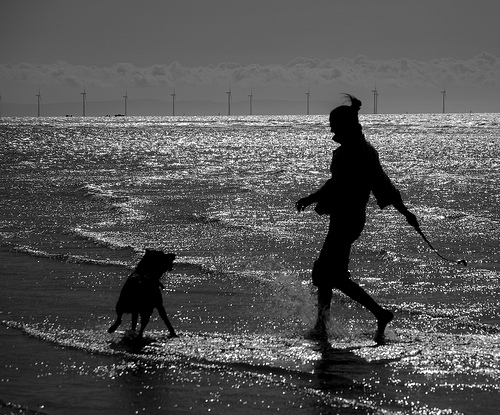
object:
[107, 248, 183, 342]
dog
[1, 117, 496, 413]
water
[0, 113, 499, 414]
beach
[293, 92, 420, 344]
woman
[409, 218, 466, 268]
leash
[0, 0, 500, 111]
sky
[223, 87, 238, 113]
windmills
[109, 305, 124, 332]
legs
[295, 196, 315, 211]
hands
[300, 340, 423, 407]
shadow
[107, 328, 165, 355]
dog's shadow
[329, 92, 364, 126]
hair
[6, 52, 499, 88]
clouds